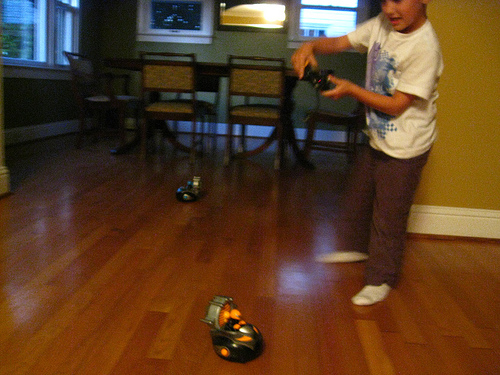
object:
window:
[0, 4, 55, 59]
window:
[48, 0, 71, 66]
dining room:
[0, 0, 382, 222]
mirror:
[215, 0, 291, 29]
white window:
[140, 4, 215, 44]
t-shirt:
[343, 7, 442, 158]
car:
[199, 288, 268, 364]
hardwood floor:
[3, 126, 495, 373]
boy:
[277, 0, 453, 306]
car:
[177, 175, 207, 202]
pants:
[352, 129, 436, 292]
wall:
[448, 7, 498, 213]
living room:
[4, 0, 496, 374]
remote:
[298, 68, 332, 90]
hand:
[326, 77, 343, 99]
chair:
[222, 53, 290, 165]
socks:
[350, 279, 394, 311]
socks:
[316, 250, 366, 269]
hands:
[290, 41, 319, 79]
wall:
[219, 33, 278, 56]